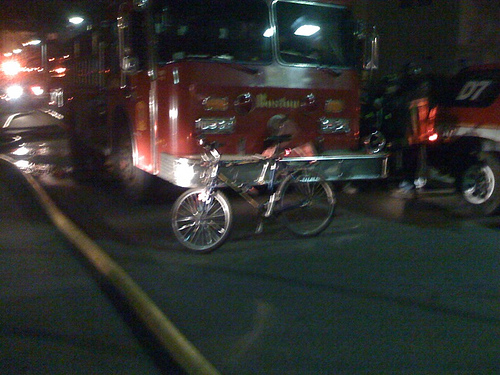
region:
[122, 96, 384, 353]
the bicycle is silver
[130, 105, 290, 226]
the bicycle is silver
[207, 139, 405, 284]
the bicycle is silver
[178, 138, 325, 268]
the bicycle is silver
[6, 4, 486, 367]
Photo was taken at night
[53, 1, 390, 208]
A red fire truck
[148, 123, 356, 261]
A bike is in front of the red fire truck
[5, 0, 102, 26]
The sky is dark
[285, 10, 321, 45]
Light is reflecting off the fire truck's windshield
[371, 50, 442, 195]
Fire men are blurred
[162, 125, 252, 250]
Light is reflecting off the silver bike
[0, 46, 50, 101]
Bright lights are in the background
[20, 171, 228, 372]
A fire hose is on the ground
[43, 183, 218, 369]
The fire hose is yellow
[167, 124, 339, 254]
a silver chrome bicycle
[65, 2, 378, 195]
front of a red fire engine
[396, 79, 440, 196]
a worker in a safety vest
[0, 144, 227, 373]
a yellow fire hose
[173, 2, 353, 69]
a fire engine windshield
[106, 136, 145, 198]
a front right tire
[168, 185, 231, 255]
a front bicycle tire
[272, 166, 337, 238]
a rear bicycle tire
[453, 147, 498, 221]
a black car tire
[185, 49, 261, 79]
a black windshield wiper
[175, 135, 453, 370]
A bicycle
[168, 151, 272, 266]
A bicycle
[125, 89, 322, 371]
A bicycle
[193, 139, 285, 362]
A bicycle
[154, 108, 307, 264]
A bicycle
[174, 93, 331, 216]
A bicycle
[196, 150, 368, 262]
A bicycle